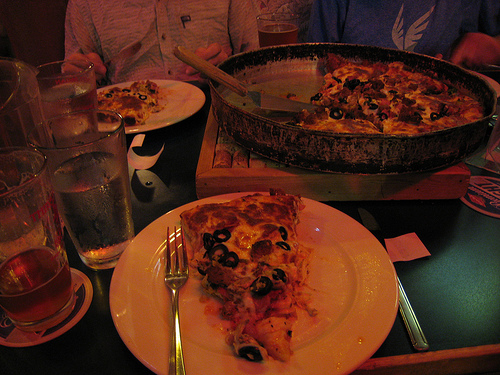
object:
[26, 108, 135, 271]
glass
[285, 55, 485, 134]
pizza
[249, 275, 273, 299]
olive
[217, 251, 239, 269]
olive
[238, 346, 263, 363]
olive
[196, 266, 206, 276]
olive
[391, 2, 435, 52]
symbol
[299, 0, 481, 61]
shirt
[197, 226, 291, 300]
toppings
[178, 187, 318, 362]
cheese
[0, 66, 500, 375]
table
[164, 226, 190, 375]
fork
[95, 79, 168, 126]
pizza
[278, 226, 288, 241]
olives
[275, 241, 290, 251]
olives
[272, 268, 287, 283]
olives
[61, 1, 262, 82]
man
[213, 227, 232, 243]
olive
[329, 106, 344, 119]
olive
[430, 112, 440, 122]
olive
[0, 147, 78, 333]
glass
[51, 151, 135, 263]
liquid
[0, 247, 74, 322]
liquid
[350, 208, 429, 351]
knife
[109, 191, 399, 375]
plate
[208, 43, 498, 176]
pan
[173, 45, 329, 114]
handle